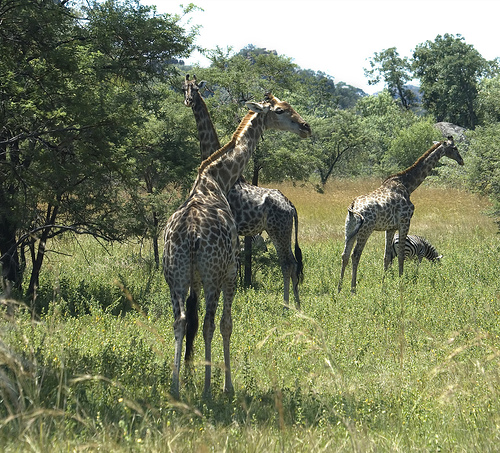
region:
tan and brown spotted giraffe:
[347, 124, 460, 274]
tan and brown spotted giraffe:
[148, 87, 300, 371]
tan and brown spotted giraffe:
[144, 58, 209, 142]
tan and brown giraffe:
[134, 85, 291, 382]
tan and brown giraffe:
[337, 123, 451, 306]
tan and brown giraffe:
[319, 123, 477, 220]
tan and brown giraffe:
[153, 64, 207, 134]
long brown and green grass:
[9, 310, 131, 383]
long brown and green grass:
[242, 292, 325, 381]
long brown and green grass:
[308, 314, 411, 419]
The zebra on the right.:
[398, 225, 448, 273]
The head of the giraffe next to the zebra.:
[441, 124, 472, 166]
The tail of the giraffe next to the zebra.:
[345, 198, 370, 245]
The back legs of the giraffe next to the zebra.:
[344, 228, 369, 290]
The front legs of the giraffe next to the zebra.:
[386, 230, 407, 281]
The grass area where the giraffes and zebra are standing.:
[36, 188, 498, 395]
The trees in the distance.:
[6, 3, 496, 197]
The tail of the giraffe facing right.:
[178, 215, 218, 349]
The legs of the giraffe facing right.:
[142, 264, 243, 417]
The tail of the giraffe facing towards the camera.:
[267, 189, 304, 280]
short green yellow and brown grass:
[266, 316, 336, 368]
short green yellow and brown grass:
[240, 347, 351, 404]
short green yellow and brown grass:
[363, 323, 466, 387]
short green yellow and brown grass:
[331, 298, 450, 331]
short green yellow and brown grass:
[16, 310, 117, 369]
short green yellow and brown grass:
[20, 354, 140, 415]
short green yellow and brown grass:
[64, 244, 130, 297]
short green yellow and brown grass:
[240, 374, 335, 428]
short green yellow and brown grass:
[291, 185, 341, 227]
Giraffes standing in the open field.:
[172, 77, 309, 372]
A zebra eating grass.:
[384, 222, 446, 276]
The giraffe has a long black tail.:
[176, 256, 193, 377]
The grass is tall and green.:
[36, 311, 382, 428]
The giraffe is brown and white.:
[173, 57, 305, 320]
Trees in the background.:
[64, 9, 478, 184]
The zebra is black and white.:
[387, 212, 444, 298]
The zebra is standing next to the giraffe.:
[341, 118, 473, 295]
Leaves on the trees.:
[47, 27, 147, 207]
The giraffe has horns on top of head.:
[247, 68, 299, 116]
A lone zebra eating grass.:
[387, 233, 445, 285]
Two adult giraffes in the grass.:
[162, 65, 312, 411]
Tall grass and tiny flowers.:
[309, 330, 489, 444]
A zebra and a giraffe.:
[335, 128, 466, 299]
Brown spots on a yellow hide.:
[202, 220, 230, 277]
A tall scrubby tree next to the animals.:
[3, 3, 151, 308]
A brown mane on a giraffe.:
[387, 138, 443, 180]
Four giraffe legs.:
[155, 271, 246, 405]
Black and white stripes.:
[410, 243, 427, 256]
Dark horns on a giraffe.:
[444, 130, 456, 145]